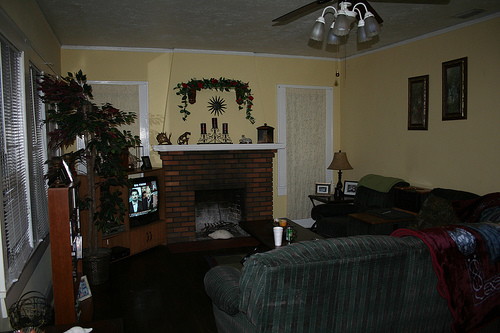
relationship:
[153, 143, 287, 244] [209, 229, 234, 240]
fire place has ashes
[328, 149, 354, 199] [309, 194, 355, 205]
lamp on table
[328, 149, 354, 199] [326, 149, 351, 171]
lamp has a shade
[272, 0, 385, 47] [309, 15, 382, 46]
ceiling fan has lights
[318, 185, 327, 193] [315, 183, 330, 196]
photo in a frame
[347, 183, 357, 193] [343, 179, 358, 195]
photo in a frame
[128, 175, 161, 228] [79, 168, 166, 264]
television in a entertainment center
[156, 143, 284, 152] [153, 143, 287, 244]
mantel on fire place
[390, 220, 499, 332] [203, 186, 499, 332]
blanket on couch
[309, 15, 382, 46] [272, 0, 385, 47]
lights on ceiling fan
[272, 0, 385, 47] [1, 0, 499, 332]
ceiling fan in room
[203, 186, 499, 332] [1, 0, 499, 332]
couch in middle of room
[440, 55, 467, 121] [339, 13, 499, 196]
picture on wall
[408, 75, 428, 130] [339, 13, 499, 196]
picture on wall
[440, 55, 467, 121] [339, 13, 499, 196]
picture hanging on wall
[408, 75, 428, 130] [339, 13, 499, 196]
picture hanging on wall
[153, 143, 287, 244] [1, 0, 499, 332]
fire place in room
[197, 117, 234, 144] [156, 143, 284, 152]
candles on top of mantel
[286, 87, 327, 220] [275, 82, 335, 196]
curtain on window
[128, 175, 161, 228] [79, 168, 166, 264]
television on entertainment center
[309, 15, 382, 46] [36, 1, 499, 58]
lights on ceiling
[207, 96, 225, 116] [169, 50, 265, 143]
sun on wall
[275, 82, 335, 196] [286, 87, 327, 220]
window has a curtain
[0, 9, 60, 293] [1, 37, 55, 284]
window has blinds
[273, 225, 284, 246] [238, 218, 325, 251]
cup on table